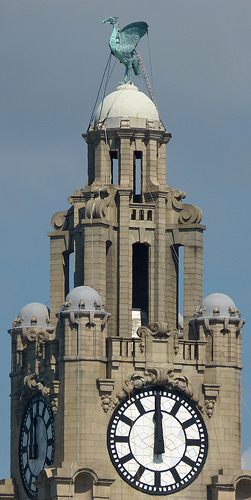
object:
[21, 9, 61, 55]
clouds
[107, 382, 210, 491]
clock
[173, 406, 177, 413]
marks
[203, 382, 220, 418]
shelf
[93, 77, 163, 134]
top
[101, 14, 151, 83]
monument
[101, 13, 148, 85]
animal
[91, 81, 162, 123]
dome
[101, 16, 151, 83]
sculpture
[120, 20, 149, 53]
wing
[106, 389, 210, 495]
face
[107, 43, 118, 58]
piece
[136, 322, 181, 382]
details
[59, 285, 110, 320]
detail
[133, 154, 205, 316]
cable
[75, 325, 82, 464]
stain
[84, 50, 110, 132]
cable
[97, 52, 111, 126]
cable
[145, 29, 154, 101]
cable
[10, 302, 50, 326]
dome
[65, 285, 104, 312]
dome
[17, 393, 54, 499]
clock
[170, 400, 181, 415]
line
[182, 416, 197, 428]
line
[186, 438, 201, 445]
line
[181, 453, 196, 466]
line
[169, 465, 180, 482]
line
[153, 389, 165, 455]
hands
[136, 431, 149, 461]
cracks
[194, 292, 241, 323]
dome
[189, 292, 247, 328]
roof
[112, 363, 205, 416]
design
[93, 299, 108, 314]
designs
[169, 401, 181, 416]
bar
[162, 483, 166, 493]
dots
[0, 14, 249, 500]
building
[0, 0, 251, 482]
sky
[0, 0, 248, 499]
scene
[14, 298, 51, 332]
caps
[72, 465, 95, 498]
arch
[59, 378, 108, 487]
wall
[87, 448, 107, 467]
stone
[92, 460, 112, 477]
stone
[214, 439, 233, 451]
stone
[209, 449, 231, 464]
stone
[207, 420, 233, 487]
wall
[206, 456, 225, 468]
stone